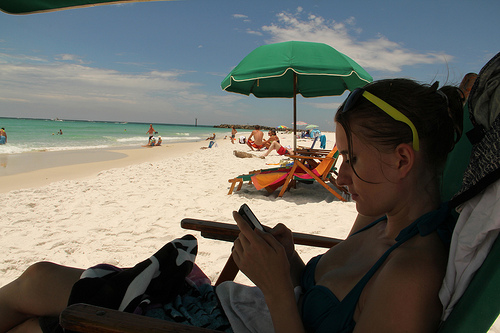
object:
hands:
[229, 208, 305, 294]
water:
[0, 120, 268, 171]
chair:
[227, 143, 348, 202]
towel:
[67, 233, 199, 317]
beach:
[0, 131, 357, 289]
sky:
[0, 0, 499, 130]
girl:
[0, 77, 468, 333]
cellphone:
[235, 203, 264, 236]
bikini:
[289, 210, 441, 332]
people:
[143, 125, 316, 160]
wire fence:
[57, 190, 155, 237]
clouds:
[0, 39, 226, 124]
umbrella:
[220, 40, 374, 99]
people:
[0, 128, 127, 145]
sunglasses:
[341, 86, 421, 152]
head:
[332, 77, 466, 217]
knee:
[19, 262, 63, 316]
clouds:
[230, 6, 456, 75]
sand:
[0, 130, 360, 297]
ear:
[393, 143, 416, 181]